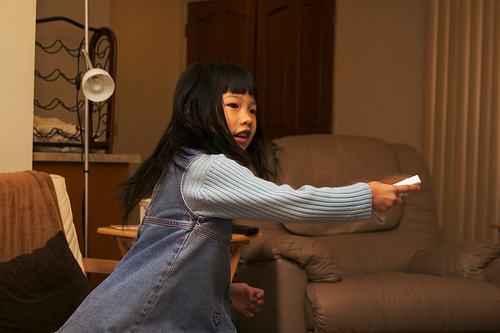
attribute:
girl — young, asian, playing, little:
[53, 59, 421, 331]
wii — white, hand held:
[371, 172, 421, 226]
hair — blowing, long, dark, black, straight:
[107, 59, 285, 231]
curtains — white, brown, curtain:
[425, 0, 499, 246]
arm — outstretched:
[202, 154, 421, 221]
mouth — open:
[233, 128, 251, 142]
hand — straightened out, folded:
[364, 180, 422, 214]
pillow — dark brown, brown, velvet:
[2, 230, 91, 332]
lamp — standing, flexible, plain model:
[78, 48, 116, 257]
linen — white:
[33, 113, 101, 154]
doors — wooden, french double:
[186, 1, 334, 143]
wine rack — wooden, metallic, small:
[35, 16, 118, 153]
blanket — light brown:
[0, 169, 66, 264]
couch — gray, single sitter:
[2, 170, 121, 332]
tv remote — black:
[231, 221, 261, 238]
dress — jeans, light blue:
[54, 146, 240, 331]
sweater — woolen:
[182, 148, 372, 221]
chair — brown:
[232, 134, 499, 332]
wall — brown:
[1, 1, 423, 182]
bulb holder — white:
[90, 75, 101, 81]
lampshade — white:
[82, 68, 116, 102]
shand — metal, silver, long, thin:
[83, 2, 89, 256]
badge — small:
[212, 310, 221, 323]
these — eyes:
[225, 101, 258, 117]